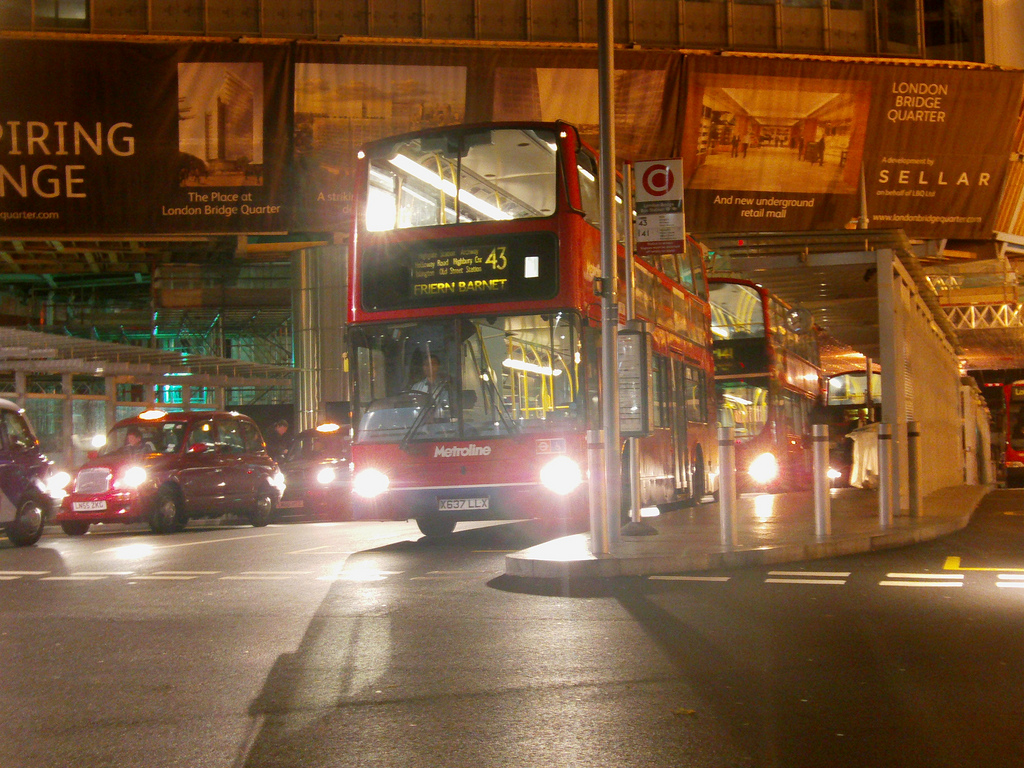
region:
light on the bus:
[358, 476, 385, 503]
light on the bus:
[533, 459, 578, 498]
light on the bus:
[754, 440, 790, 482]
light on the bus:
[117, 397, 174, 421]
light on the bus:
[514, 253, 549, 282]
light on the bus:
[729, 454, 821, 481]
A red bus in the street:
[345, 124, 713, 530]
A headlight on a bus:
[533, 451, 581, 505]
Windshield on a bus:
[352, 303, 583, 437]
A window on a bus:
[358, 129, 558, 232]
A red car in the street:
[54, 402, 290, 527]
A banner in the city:
[1, 31, 1022, 250]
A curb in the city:
[504, 480, 992, 582]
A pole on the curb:
[588, 6, 630, 566]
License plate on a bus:
[424, 495, 495, 516]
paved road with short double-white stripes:
[1, 520, 1014, 755]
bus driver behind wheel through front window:
[346, 311, 465, 439]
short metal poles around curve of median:
[504, 411, 931, 586]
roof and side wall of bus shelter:
[671, 218, 966, 528]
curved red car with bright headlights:
[45, 403, 290, 550]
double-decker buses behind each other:
[349, 114, 884, 545]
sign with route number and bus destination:
[352, 218, 564, 318]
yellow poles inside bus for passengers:
[504, 329, 577, 424]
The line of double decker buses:
[341, 102, 889, 548]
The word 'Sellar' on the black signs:
[871, 159, 1002, 198]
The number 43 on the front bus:
[477, 238, 516, 277]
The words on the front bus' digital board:
[392, 238, 520, 302]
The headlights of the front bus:
[345, 450, 590, 512]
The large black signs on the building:
[0, 28, 1010, 241]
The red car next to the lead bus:
[56, 398, 297, 536]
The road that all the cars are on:
[0, 482, 1022, 764]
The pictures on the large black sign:
[161, 48, 876, 205]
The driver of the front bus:
[401, 346, 462, 432]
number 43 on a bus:
[484, 241, 511, 280]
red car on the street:
[56, 395, 295, 555]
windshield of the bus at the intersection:
[343, 319, 591, 459]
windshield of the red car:
[101, 420, 194, 472]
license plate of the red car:
[70, 496, 115, 520]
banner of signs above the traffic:
[3, 29, 1007, 257]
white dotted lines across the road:
[2, 553, 1021, 617]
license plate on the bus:
[430, 490, 500, 516]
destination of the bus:
[400, 246, 512, 295]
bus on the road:
[329, 98, 707, 574]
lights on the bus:
[335, 432, 595, 521]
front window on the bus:
[332, 288, 563, 472]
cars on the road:
[13, 375, 334, 534]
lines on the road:
[715, 527, 992, 610]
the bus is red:
[310, 89, 707, 555]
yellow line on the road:
[919, 543, 1017, 573]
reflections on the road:
[60, 497, 473, 748]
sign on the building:
[367, 233, 526, 304]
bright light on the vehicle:
[349, 463, 387, 506]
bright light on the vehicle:
[741, 447, 777, 485]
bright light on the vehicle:
[117, 463, 147, 487]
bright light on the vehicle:
[39, 463, 68, 499]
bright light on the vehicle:
[258, 466, 282, 496]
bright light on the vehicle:
[822, 463, 841, 487]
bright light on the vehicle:
[538, 447, 584, 505]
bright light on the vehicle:
[351, 462, 393, 504]